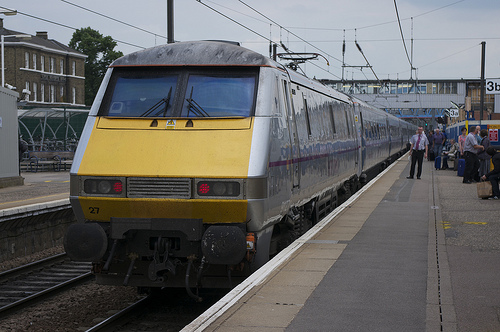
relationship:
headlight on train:
[80, 174, 243, 203] [58, 44, 434, 292]